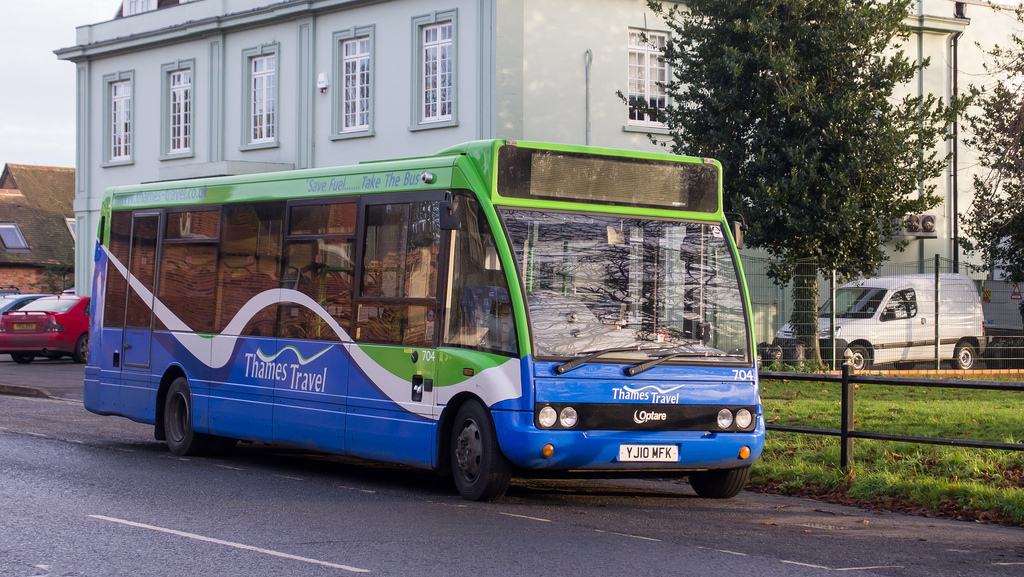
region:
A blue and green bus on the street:
[85, 140, 769, 494]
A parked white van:
[771, 273, 991, 381]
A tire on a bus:
[442, 396, 513, 508]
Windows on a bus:
[101, 186, 437, 345]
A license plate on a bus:
[610, 436, 678, 471]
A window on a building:
[157, 54, 196, 159]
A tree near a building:
[624, 4, 953, 355]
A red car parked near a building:
[0, 285, 92, 361]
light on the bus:
[535, 404, 556, 428]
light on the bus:
[558, 401, 581, 436]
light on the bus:
[708, 402, 738, 432]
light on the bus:
[735, 407, 758, 427]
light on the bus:
[734, 436, 766, 471]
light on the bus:
[526, 433, 562, 460]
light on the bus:
[807, 326, 827, 334]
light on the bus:
[454, 353, 486, 380]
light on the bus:
[415, 171, 447, 191]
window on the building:
[421, 40, 463, 120]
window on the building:
[332, 32, 372, 137]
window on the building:
[152, 53, 195, 151]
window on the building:
[105, 69, 153, 164]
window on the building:
[630, 32, 681, 135]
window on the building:
[754, 306, 781, 345]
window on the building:
[977, 54, 1020, 131]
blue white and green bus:
[54, 164, 949, 515]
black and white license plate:
[582, 439, 748, 493]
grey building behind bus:
[47, 0, 948, 361]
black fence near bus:
[771, 339, 1022, 473]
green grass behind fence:
[786, 380, 1022, 524]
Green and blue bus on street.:
[58, 137, 764, 496]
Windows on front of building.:
[70, 5, 473, 168]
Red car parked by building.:
[0, 292, 93, 360]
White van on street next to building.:
[778, 271, 985, 370]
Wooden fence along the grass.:
[766, 358, 1022, 473]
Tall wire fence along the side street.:
[746, 254, 1022, 373]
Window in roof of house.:
[1, 211, 33, 259]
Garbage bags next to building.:
[759, 339, 813, 372]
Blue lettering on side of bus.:
[285, 167, 440, 196]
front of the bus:
[367, 121, 832, 526]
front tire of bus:
[375, 364, 552, 533]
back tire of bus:
[103, 347, 262, 499]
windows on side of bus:
[65, 173, 524, 409]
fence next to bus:
[754, 300, 986, 501]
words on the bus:
[572, 342, 725, 440]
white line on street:
[87, 487, 326, 570]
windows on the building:
[38, 3, 491, 199]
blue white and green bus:
[61, 115, 777, 507]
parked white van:
[760, 243, 995, 384]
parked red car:
[0, 266, 112, 375]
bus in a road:
[9, 133, 1019, 574]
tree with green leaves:
[617, 4, 973, 378]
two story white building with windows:
[46, 0, 1021, 378]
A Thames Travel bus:
[68, 128, 790, 518]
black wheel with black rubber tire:
[428, 387, 518, 502]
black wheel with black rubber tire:
[138, 368, 211, 457]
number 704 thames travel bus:
[53, 130, 784, 495]